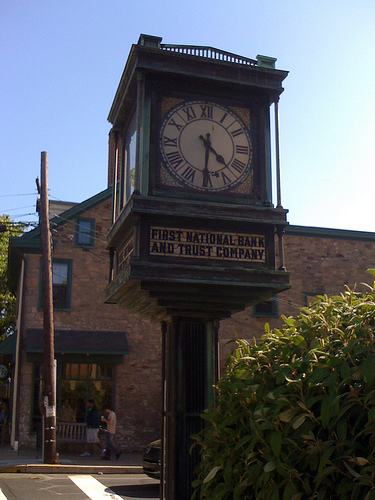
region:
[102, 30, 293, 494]
Black clock tower pole on the sidewalk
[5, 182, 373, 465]
Large brown brick building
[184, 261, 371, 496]
Green bush with leaves to the right of the clock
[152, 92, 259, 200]
Face of the clock on the pole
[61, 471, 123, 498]
Wide white stripe on the road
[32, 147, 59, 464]
Telephone and power pole on the street corner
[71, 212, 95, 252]
Small window in the brick building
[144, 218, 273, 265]
Sign under the clock face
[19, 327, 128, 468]
Large window on the bottom floor of the building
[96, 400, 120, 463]
Male wearing a beige shirt in front of the building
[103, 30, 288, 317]
elevated clock and lettering set in boxy and heavy frame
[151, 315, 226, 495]
thick ridged column under clock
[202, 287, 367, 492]
curved bush covered in green leaves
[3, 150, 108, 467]
large wooden pole supporting wires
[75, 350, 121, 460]
people walking in front of a window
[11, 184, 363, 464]
stone building with green trim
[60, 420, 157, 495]
front of car waiting behind white line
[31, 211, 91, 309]
rectangular windows on different elevations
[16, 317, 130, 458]
dark awning over wooden bench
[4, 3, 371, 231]
blue and white sky behind clocktower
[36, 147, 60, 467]
Telephone pole on the sidewalk.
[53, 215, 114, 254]
Phone wires on the pole.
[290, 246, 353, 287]
Large brown brick building.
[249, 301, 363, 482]
Green bush on this side of the street.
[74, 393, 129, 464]
Two people walking on the sidewalk.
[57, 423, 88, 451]
Bench beneath a large window.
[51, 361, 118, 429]
Large window in the building.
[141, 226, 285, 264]
The bank is sponsoring the clock.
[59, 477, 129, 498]
White line on the street.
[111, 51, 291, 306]
Large clock on the sidewalk.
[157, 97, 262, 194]
clock face with roman numerals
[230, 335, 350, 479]
green leaves on a hedge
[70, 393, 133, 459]
two pedestrians on the sidewalk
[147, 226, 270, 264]
sign underneath a clock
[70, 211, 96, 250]
small window on a building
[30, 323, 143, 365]
canopy over a store front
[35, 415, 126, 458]
wooden bench on the sidewalk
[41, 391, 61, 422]
signs posted on a light post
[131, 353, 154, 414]
brick wall on a building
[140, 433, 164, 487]
front of a vehicle in the road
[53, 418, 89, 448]
a bench in front of a window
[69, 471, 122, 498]
a white line on a road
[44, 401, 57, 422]
a paper attached to a pole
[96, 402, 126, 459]
a man carrying a drink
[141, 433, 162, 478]
the front end of a vehicle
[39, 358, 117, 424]
a large window in a building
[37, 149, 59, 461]
a tall brown utility pole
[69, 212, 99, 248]
an upstairs window in a building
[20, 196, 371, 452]
a brick building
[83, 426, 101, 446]
white shorts on a man